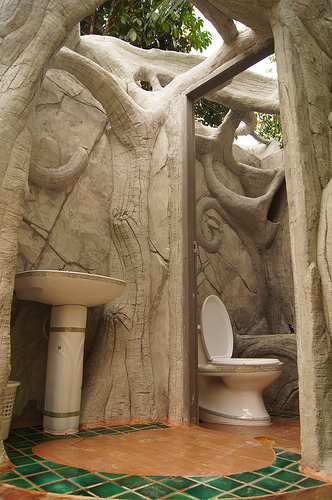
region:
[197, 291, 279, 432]
white toilet in bathroom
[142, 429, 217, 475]
light brown wooden floor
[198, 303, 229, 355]
toilet lid is raised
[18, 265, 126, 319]
white sink in bathroom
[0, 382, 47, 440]
white basket near sink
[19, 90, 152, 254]
stone walls around sink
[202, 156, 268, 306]
brown stone walls around toilet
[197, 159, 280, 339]
walls have tree-like carvings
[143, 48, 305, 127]
green trees above bathroom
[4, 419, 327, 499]
green tile on a bathroom floor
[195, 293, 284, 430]
a decorative toilet in a bathroom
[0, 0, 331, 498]
a bathroom with a nature design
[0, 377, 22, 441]
a laundry basket under a sink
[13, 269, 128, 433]
a decorative bathroom sink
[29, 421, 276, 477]
a brown circular area on a bathroom floor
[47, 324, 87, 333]
a stripe on a sink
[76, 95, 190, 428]
a wall designed like a wooden trunk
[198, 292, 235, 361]
an uplifted toilet seat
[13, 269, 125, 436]
sink near the wall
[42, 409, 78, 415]
dark stripe on sink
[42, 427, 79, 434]
light brown cement on sink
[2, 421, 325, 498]
the tiles are green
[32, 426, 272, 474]
brown circular shape on floor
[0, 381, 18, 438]
the basket is white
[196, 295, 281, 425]
the toilet is white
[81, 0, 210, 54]
tree above the bathroom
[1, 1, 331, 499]
bathroom is inside a tree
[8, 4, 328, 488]
the bathroom is an open air structure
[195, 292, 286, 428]
a toilet is in the bathroom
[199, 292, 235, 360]
the lid is up on the toilet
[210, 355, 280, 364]
the seat of the toilet is down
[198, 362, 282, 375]
a decorative edge is around the toilet bowl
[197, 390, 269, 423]
the base of the john has a decorative edge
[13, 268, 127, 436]
a pedestal sink is in the outdoor room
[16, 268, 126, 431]
decorative edges are on the sink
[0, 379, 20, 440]
a waste basket is under the sink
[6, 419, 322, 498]
green inlaid tile is in the floor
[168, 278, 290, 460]
this is a toilet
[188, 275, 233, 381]
this is a toilet seat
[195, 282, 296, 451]
this is a white toilet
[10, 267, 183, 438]
this is a sink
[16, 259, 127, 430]
this is a white sink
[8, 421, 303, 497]
this is the floor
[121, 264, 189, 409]
this is a wall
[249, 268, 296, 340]
this is a wall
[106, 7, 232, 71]
this is a green vegetation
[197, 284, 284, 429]
a toilet on the side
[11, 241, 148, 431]
an outside white sink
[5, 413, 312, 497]
tile on the floor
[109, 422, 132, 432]
a tile in a floor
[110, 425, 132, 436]
a tile in a floor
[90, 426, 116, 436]
a tile in a floor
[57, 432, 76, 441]
a tile in a floor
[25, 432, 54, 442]
a tile in a floor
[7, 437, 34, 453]
a tile in a floor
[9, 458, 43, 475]
a tile in a floor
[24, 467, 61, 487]
a tile in a floor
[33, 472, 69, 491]
a tile in a floor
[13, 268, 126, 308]
A sink sitting on top of a pedestal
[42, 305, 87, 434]
A pedestal holding up a sink